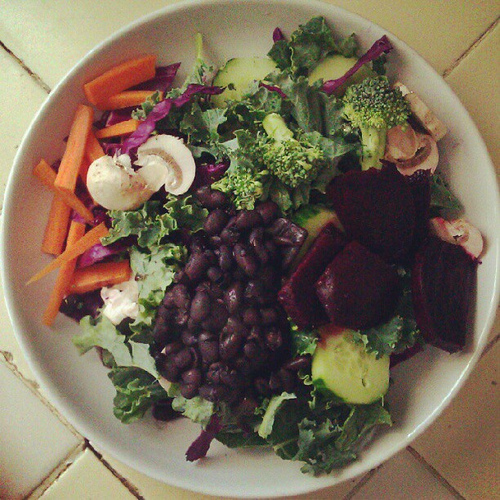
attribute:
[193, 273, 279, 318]
beans — black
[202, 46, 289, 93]
lettuce — green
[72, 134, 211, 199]
mushrooms — white, sliced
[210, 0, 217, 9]
plate — white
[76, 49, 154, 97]
carrots — orange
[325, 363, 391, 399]
cucumber — green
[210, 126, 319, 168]
broccoli — green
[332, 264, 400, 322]
cabbage — red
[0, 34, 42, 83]
tile — grime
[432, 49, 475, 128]
bowl — white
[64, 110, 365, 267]
salad — green, large